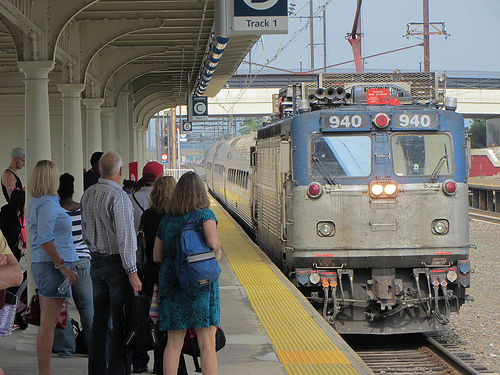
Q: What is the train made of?
A: Metal.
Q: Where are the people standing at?
A: The platform.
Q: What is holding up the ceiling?
A: Columns.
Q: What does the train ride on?
A: Tracks.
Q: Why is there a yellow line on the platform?
A: Safety.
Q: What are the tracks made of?
A: Metal.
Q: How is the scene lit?
A: Daylight.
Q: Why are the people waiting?
A: Train to stop.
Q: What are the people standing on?
A: The platform.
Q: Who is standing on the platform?
A: Travellers.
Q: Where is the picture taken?
A: A train station.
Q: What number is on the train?
A: 940.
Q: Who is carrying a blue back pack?
A: A woman in blue.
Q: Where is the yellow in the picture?
A: Lining the tracks.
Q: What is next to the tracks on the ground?
A: Gravel.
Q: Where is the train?
A: On the tracks.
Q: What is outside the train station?
A: City buildings.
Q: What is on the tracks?
A: A train.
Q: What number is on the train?
A: 940.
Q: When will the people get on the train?
A: When the doors are open.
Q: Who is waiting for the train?
A: The crowd of people.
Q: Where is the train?
A: On the tracks.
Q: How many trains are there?
A: One.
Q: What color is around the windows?
A: Blue.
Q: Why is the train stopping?
A: So the people can get on.